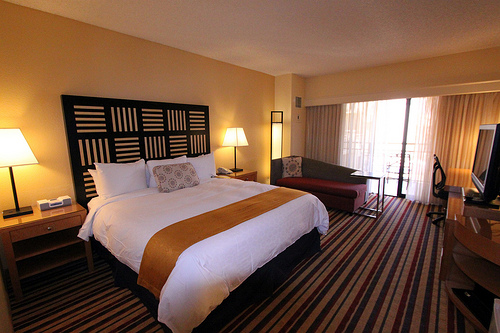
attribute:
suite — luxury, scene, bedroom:
[6, 67, 380, 293]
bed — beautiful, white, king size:
[97, 149, 323, 288]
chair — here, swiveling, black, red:
[296, 179, 335, 204]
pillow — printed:
[271, 147, 299, 180]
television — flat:
[457, 134, 494, 212]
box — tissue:
[28, 229, 70, 244]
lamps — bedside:
[0, 163, 28, 212]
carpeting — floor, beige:
[303, 279, 347, 300]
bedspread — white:
[134, 202, 183, 217]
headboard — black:
[102, 106, 155, 164]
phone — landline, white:
[215, 161, 235, 173]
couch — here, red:
[260, 159, 335, 198]